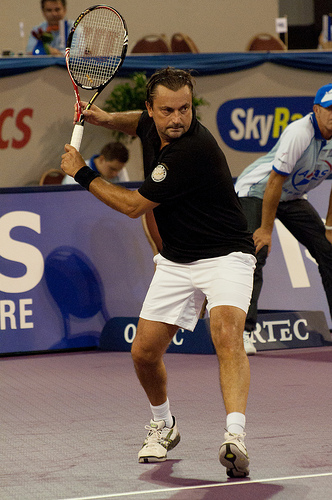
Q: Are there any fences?
A: No, there are no fences.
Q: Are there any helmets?
A: No, there are no helmets.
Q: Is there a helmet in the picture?
A: No, there are no helmets.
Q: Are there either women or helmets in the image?
A: No, there are no helmets or women.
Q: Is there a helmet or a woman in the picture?
A: No, there are no helmets or women.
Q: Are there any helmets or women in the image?
A: No, there are no helmets or women.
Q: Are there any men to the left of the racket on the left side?
A: Yes, there is a man to the left of the racket.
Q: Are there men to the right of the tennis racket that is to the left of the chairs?
A: No, the man is to the left of the tennis racket.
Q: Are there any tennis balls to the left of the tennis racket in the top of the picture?
A: No, there is a man to the left of the racket.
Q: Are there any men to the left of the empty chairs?
A: Yes, there is a man to the left of the chairs.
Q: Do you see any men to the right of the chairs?
A: No, the man is to the left of the chairs.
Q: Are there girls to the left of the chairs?
A: No, there is a man to the left of the chairs.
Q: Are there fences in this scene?
A: No, there are no fences.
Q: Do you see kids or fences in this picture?
A: No, there are no fences or kids.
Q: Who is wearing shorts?
A: The man is wearing shorts.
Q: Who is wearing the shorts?
A: The man is wearing shorts.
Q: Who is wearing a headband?
A: The man is wearing a headband.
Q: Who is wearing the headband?
A: The man is wearing a headband.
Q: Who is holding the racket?
A: The man is holding the racket.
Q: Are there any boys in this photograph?
A: No, there are no boys.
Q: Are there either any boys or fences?
A: No, there are no boys or fences.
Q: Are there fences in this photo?
A: No, there are no fences.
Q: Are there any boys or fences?
A: No, there are no fences or boys.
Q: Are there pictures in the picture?
A: No, there are no pictures.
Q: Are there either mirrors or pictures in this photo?
A: No, there are no pictures or mirrors.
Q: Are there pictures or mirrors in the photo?
A: No, there are no pictures or mirrors.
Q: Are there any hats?
A: Yes, there is a hat.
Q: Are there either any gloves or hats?
A: Yes, there is a hat.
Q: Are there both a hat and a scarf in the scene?
A: No, there is a hat but no scarves.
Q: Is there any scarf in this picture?
A: No, there are no scarves.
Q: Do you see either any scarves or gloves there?
A: No, there are no scarves or gloves.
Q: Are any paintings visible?
A: No, there are no paintings.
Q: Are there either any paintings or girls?
A: No, there are no paintings or girls.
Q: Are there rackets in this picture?
A: Yes, there is a racket.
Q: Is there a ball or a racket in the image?
A: Yes, there is a racket.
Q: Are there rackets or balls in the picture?
A: Yes, there is a racket.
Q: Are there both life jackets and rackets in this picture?
A: No, there is a racket but no life jackets.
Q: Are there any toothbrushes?
A: No, there are no toothbrushes.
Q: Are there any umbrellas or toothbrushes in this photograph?
A: No, there are no toothbrushes or umbrellas.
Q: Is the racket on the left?
A: Yes, the racket is on the left of the image.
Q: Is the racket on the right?
A: No, the racket is on the left of the image.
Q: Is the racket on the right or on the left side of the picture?
A: The racket is on the left of the image.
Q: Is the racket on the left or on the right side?
A: The racket is on the left of the image.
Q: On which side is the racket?
A: The racket is on the left of the image.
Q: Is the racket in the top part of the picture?
A: Yes, the racket is in the top of the image.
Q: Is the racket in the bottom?
A: No, the racket is in the top of the image.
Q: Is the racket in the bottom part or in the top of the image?
A: The racket is in the top of the image.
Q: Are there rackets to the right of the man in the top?
A: Yes, there is a racket to the right of the man.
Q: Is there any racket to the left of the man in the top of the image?
A: No, the racket is to the right of the man.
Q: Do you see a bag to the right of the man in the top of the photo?
A: No, there is a racket to the right of the man.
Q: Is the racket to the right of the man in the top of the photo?
A: Yes, the racket is to the right of the man.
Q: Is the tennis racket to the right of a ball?
A: No, the tennis racket is to the right of the man.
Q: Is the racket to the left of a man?
A: No, the racket is to the right of a man.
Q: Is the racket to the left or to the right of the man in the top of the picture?
A: The racket is to the right of the man.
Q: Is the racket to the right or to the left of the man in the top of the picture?
A: The racket is to the right of the man.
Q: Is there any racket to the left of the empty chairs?
A: Yes, there is a racket to the left of the chairs.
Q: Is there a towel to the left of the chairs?
A: No, there is a racket to the left of the chairs.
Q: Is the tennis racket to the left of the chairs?
A: Yes, the tennis racket is to the left of the chairs.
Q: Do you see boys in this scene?
A: No, there are no boys.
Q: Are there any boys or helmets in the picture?
A: No, there are no boys or helmets.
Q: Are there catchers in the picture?
A: No, there are no catchers.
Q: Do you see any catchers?
A: No, there are no catchers.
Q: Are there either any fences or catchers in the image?
A: No, there are no catchers or fences.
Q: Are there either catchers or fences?
A: No, there are no catchers or fences.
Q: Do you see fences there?
A: No, there are no fences.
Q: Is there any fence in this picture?
A: No, there are no fences.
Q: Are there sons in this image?
A: No, there are no sons.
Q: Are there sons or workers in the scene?
A: No, there are no sons or workers.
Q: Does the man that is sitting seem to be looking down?
A: Yes, the man is looking down.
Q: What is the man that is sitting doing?
A: The man is looking down.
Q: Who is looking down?
A: The man is looking down.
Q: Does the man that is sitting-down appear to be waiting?
A: No, the man is looking down.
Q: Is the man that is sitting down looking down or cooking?
A: The man is looking down.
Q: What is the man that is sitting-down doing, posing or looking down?
A: The man is looking down.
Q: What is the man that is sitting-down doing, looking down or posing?
A: The man is looking down.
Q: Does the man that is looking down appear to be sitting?
A: Yes, the man is sitting.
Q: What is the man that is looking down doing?
A: The man is sitting.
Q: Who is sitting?
A: The man is sitting.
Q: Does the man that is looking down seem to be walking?
A: No, the man is sitting.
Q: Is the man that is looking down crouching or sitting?
A: The man is sitting.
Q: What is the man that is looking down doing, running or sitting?
A: The man is sitting.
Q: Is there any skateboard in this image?
A: No, there are no skateboards.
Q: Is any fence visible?
A: No, there are no fences.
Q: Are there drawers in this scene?
A: No, there are no drawers.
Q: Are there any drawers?
A: No, there are no drawers.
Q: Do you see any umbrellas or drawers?
A: No, there are no drawers or umbrellas.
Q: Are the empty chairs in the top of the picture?
A: Yes, the chairs are in the top of the image.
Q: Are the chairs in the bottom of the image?
A: No, the chairs are in the top of the image.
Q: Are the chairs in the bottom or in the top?
A: The chairs are in the top of the image.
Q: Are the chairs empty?
A: Yes, the chairs are empty.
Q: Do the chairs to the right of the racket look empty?
A: Yes, the chairs are empty.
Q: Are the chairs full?
A: No, the chairs are empty.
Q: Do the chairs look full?
A: No, the chairs are empty.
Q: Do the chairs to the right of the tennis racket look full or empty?
A: The chairs are empty.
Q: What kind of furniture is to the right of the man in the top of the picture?
A: The pieces of furniture are chairs.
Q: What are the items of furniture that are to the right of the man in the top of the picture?
A: The pieces of furniture are chairs.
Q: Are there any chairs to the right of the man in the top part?
A: Yes, there are chairs to the right of the man.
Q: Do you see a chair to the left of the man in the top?
A: No, the chairs are to the right of the man.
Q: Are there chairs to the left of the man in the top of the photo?
A: No, the chairs are to the right of the man.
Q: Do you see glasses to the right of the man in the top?
A: No, there are chairs to the right of the man.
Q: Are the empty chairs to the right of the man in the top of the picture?
A: Yes, the chairs are to the right of the man.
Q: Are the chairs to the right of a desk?
A: No, the chairs are to the right of the man.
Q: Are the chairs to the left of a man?
A: No, the chairs are to the right of a man.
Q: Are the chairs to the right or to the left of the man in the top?
A: The chairs are to the right of the man.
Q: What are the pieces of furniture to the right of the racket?
A: The pieces of furniture are chairs.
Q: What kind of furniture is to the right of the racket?
A: The pieces of furniture are chairs.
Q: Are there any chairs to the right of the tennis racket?
A: Yes, there are chairs to the right of the tennis racket.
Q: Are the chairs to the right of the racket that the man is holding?
A: Yes, the chairs are to the right of the racket.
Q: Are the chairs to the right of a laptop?
A: No, the chairs are to the right of the racket.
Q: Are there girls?
A: No, there are no girls.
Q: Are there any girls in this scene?
A: No, there are no girls.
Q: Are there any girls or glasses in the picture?
A: No, there are no girls or glasses.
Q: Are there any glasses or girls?
A: No, there are no girls or glasses.